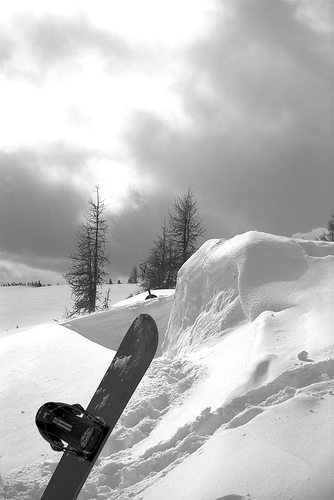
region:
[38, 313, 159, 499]
a black snowboard in the snow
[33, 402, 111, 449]
a black snowboard binding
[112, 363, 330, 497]
tracks in the snow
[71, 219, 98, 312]
a bare tree in the snow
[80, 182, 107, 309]
a bare tree in the snow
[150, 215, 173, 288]
a bare tree in the snow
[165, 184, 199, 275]
a bare tree in the snow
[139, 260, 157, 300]
a shovel handle in the distance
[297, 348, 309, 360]
a clump of snow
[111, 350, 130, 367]
snow on the snowboard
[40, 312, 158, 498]
grey snowboard standing up in the snow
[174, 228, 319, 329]
snow covered rock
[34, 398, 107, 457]
black boot strap on snowboard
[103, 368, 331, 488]
foot prints in snow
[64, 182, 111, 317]
barren trees on mountain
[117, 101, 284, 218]
dark clouds in sky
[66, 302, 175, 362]
shadow made by hill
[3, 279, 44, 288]
forest in the distance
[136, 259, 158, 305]
shovel stuck in the snow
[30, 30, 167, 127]
sun trying to break through clouds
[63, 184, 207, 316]
Pine trees on a snowy hillside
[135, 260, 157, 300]
A shovel sticking out of the snow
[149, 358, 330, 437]
Tracks in the snow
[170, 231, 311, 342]
A snow drift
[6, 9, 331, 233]
Sky filled with dark clouds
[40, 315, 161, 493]
A lone ski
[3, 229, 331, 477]
A snow filled landscape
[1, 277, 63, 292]
Trees on a ridge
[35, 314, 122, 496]
A boot attached to a snow board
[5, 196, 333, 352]
White snow under a cloudy sky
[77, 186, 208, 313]
several trees in photogaph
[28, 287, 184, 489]
snow board staiding in snow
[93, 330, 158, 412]
snow on snow board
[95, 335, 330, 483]
several sets of tracks in snow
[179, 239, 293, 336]
snow piled high in photo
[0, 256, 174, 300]
line of trees on horizon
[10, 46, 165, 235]
sun peeking through clouds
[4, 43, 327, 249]
mostly cloudy skies in photograph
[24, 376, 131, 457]
boot holder on black snowboard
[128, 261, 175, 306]
something black standing in snow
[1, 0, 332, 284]
Bright cloudy sky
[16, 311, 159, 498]
Dark snowboad with boot binding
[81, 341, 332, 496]
Foot prints in deep snow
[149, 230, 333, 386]
Big snow bank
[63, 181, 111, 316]
Tree with no leaves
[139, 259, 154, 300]
Snow shovel stuck into the snow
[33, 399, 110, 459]
Snowboard boot binding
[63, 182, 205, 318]
Trees with no leaves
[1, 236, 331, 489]
Snow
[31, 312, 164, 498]
Snowboard stuck vertically in the snow